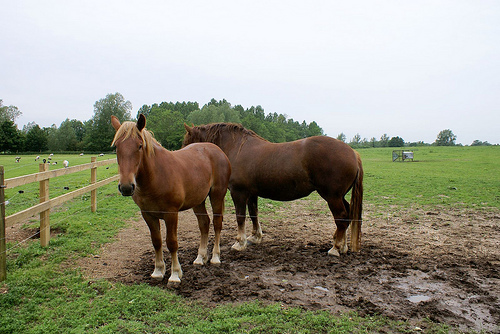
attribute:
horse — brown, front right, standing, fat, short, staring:
[110, 114, 231, 287]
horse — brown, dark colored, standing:
[180, 122, 363, 257]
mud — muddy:
[131, 235, 498, 333]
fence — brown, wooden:
[0, 156, 119, 282]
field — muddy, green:
[0, 145, 499, 333]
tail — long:
[349, 149, 364, 253]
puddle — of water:
[406, 295, 429, 304]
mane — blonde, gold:
[111, 120, 161, 159]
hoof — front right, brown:
[166, 279, 182, 290]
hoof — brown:
[150, 275, 164, 283]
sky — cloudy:
[0, 0, 499, 147]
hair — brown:
[181, 123, 267, 157]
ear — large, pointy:
[136, 114, 147, 132]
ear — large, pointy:
[109, 116, 121, 132]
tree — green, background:
[185, 102, 242, 128]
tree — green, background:
[245, 105, 264, 120]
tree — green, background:
[25, 124, 50, 151]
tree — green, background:
[55, 120, 77, 152]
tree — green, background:
[388, 136, 404, 147]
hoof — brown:
[209, 259, 220, 267]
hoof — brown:
[192, 262, 204, 269]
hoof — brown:
[229, 246, 239, 252]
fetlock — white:
[168, 264, 181, 274]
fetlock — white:
[153, 257, 165, 268]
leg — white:
[164, 212, 184, 282]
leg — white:
[139, 210, 166, 286]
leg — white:
[209, 187, 225, 264]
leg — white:
[192, 199, 210, 265]